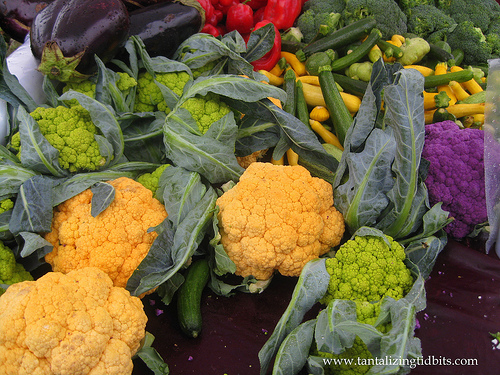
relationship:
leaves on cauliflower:
[149, 115, 324, 293] [20, 165, 179, 329]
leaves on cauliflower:
[374, 70, 499, 255] [422, 115, 499, 229]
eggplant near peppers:
[2, 4, 226, 79] [194, 0, 361, 86]